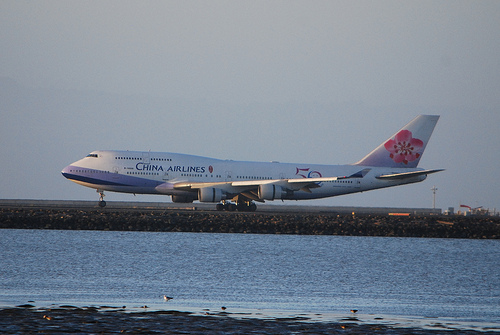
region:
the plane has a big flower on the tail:
[49, 70, 480, 281]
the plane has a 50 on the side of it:
[289, 154, 328, 231]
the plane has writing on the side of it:
[46, 99, 467, 224]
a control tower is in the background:
[427, 184, 446, 214]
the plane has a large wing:
[156, 168, 361, 203]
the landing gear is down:
[83, 182, 113, 212]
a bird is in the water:
[153, 291, 178, 300]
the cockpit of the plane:
[83, 142, 103, 167]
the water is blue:
[27, 234, 460, 296]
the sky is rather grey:
[196, 72, 356, 111]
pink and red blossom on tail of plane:
[365, 81, 442, 176]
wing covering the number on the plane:
[281, 165, 336, 195]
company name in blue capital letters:
[116, 155, 206, 180]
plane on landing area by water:
[25, 195, 435, 250]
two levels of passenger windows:
[106, 150, 211, 180]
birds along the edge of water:
[95, 281, 365, 331]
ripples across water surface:
[65, 225, 385, 305]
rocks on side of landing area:
[91, 200, 391, 236]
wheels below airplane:
[80, 190, 260, 215]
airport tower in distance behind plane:
[402, 165, 444, 215]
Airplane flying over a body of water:
[61, 115, 442, 216]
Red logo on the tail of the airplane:
[382, 126, 424, 166]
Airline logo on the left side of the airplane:
[135, 160, 213, 175]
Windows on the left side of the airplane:
[115, 153, 172, 161]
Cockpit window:
[86, 151, 97, 157]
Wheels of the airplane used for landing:
[93, 196, 253, 211]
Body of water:
[0, 226, 496, 316]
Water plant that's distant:
[430, 182, 437, 207]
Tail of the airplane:
[351, 112, 439, 165]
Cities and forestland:
[1, 201, 496, 241]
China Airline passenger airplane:
[132, 158, 222, 180]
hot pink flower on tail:
[385, 127, 440, 171]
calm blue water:
[18, 227, 493, 303]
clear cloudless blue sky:
[35, 26, 415, 129]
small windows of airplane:
[123, 164, 163, 180]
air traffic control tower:
[427, 177, 443, 209]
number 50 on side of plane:
[289, 160, 328, 195]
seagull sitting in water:
[159, 287, 179, 305]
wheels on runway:
[83, 183, 253, 215]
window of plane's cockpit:
[72, 144, 112, 170]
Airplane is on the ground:
[57, 100, 458, 237]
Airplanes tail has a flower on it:
[373, 115, 434, 168]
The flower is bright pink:
[357, 102, 442, 174]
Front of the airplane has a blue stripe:
[45, 138, 164, 199]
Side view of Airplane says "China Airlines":
[123, 155, 218, 180]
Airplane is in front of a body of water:
[2, 101, 497, 323]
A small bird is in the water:
[117, 282, 197, 312]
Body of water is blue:
[6, 229, 496, 315]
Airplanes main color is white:
[41, 133, 483, 220]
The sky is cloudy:
[8, 6, 497, 195]